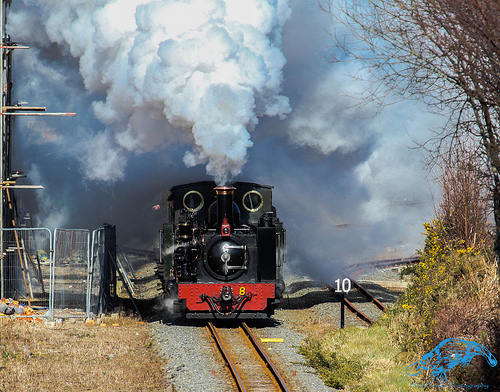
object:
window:
[244, 189, 264, 211]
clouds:
[15, 13, 433, 253]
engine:
[204, 183, 249, 222]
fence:
[5, 225, 117, 316]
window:
[182, 191, 206, 213]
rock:
[182, 338, 188, 343]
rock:
[172, 361, 182, 372]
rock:
[303, 376, 310, 382]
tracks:
[206, 317, 292, 389]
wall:
[100, 54, 173, 104]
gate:
[2, 219, 117, 321]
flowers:
[379, 210, 498, 356]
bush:
[392, 210, 497, 370]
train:
[152, 179, 287, 326]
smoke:
[11, 0, 289, 178]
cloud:
[278, 11, 453, 263]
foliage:
[401, 219, 489, 370]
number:
[237, 284, 247, 296]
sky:
[31, 10, 362, 185]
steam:
[9, 5, 487, 272]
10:
[335, 276, 351, 294]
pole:
[337, 292, 350, 328]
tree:
[327, 0, 499, 237]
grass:
[307, 331, 407, 389]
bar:
[259, 335, 284, 342]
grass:
[0, 299, 168, 390]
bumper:
[178, 282, 278, 314]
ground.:
[12, 320, 165, 390]